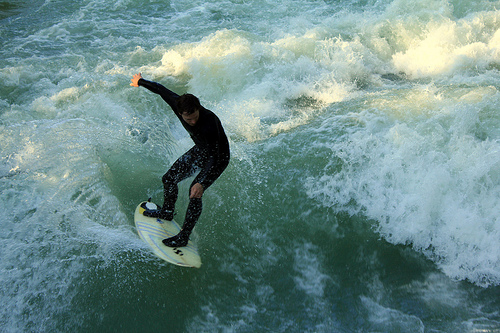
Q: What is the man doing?
A: Surfing.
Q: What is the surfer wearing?
A: A wetsuit.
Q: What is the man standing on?
A: Surfboard.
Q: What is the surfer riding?
A: Wave.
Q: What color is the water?
A: Green and white.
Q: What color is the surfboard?
A: Yellow and blue.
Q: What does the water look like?
A: Choppy.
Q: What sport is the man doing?
A: Surfing.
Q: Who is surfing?
A: The man.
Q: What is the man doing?
A: Surfing.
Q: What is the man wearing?
A: Wet suit.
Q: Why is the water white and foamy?
A: Because of the waves and rolling.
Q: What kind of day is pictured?
A: Sunny.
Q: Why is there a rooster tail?
A: It is made by the surfboard cutting the water.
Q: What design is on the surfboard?
A: Stripes.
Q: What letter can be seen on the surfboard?
A: S.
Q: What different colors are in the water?
A: Green and white.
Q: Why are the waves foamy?
A: The water is churning.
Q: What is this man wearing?
A: A black wetsuit.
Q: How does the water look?
A: Very rough looking.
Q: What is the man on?
A: A surfboard.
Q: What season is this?
A: Summer.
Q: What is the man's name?
A: Greg.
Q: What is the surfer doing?
A: Riding waves.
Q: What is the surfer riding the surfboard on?
A: Big waves.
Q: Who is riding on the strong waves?
A: A surfer.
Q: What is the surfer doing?
A: Riding waves.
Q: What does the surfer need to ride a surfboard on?
A: Water.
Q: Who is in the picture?
A: A surfer.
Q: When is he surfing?
A: During the day.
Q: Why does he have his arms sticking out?
A: To keep his balance.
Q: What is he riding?
A: A surfboard.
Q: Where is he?
A: In the ocean.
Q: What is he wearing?
A: A wetsuit.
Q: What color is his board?
A: Yellow.